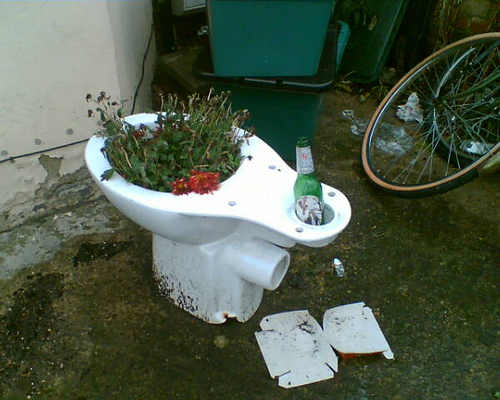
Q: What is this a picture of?
A: Toilet.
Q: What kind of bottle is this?
A: Beer.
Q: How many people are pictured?
A: 0.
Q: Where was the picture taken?
A: Yard.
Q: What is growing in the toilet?
A: Flowers.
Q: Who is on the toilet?
A: Nobody.